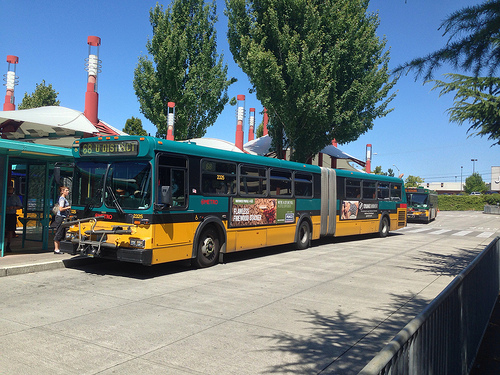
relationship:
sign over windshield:
[82, 137, 140, 157] [59, 160, 166, 225]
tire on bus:
[192, 217, 222, 268] [56, 129, 410, 281]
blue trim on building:
[0, 131, 87, 161] [4, 110, 107, 261]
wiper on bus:
[100, 161, 127, 214] [57, 133, 409, 266]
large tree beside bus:
[224, 1, 401, 163] [57, 133, 409, 266]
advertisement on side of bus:
[214, 185, 311, 227] [74, 135, 406, 253]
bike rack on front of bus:
[55, 210, 134, 262] [74, 135, 406, 253]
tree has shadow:
[434, 14, 484, 136] [286, 248, 484, 348]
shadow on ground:
[286, 248, 484, 348] [111, 295, 211, 348]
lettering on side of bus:
[198, 197, 219, 205] [56, 129, 410, 281]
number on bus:
[80, 142, 94, 153] [56, 129, 410, 281]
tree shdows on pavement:
[248, 248, 496, 374] [1, 212, 498, 374]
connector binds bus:
[319, 165, 336, 239] [57, 133, 409, 266]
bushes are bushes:
[437, 194, 499, 211] [437, 194, 499, 211]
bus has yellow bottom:
[56, 129, 410, 281] [63, 201, 412, 266]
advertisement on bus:
[228, 198, 296, 229] [69, 131, 432, 271]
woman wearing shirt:
[44, 181, 74, 255] [51, 192, 76, 231]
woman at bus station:
[54, 187, 72, 255] [1, 135, 82, 262]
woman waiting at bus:
[54, 187, 72, 255] [56, 129, 410, 281]